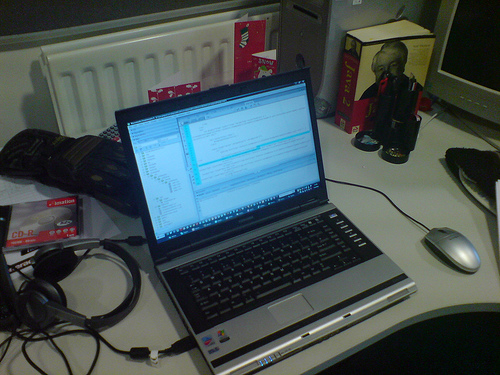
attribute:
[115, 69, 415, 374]
laptop — older, computer, on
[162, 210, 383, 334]
keyboard — laptop, computer, black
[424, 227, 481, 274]
mouse — computer, silver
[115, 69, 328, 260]
monitor — on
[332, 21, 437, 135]
book — here, titled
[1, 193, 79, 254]
case — cr-r, recordable cd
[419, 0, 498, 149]
monitor — old, crt, pictured, off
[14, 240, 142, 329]
earphone — cableless, a pair, stereo, black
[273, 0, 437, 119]
desktop — older, macintosh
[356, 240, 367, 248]
button — pictured, black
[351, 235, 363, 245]
button — pictured, black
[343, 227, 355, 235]
button — pictured, black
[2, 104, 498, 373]
table — pictured, white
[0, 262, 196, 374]
cable — usb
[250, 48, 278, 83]
card — christmas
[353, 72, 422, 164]
holder — black, organizer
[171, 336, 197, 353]
connector — usb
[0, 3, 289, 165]
wall — white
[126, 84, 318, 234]
screen — pictured